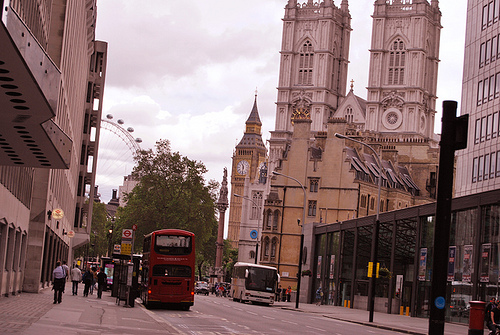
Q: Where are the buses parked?
A: On either side of the street.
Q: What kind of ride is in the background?
A: A ferris wheel.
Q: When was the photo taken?
A: Daytime.